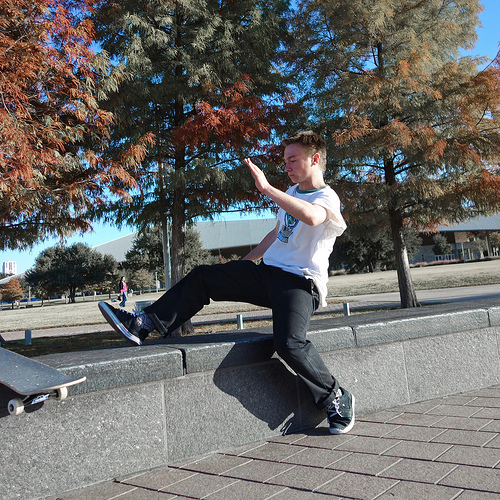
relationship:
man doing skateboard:
[94, 127, 372, 438] [0, 322, 91, 414]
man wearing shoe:
[94, 127, 372, 438] [325, 385, 358, 437]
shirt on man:
[257, 185, 347, 304] [76, 119, 363, 442]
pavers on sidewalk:
[240, 443, 467, 482] [183, 385, 484, 491]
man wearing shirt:
[94, 127, 372, 438] [257, 185, 347, 301]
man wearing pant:
[94, 127, 372, 438] [144, 257, 340, 414]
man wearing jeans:
[94, 127, 372, 438] [132, 259, 335, 408]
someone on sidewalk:
[114, 271, 133, 306] [127, 299, 158, 313]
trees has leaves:
[335, 2, 497, 307] [191, 20, 223, 51]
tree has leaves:
[87, 3, 327, 336] [393, 54, 424, 84]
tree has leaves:
[2, 2, 145, 229] [38, 10, 62, 35]